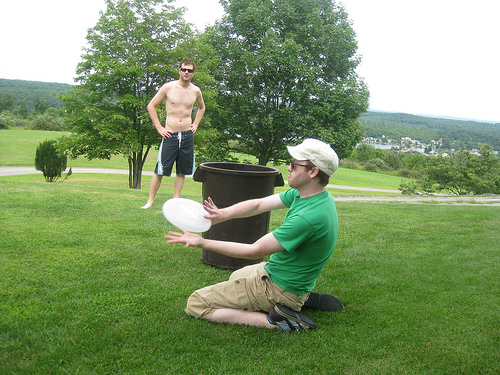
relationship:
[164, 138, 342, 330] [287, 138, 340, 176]
man wearing hat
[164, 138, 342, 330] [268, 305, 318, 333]
man wearing shoe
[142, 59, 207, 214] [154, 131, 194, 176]
man wearing shorts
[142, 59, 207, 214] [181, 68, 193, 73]
man wearing sunglasses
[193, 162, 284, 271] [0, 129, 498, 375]
garbage can sitting on grass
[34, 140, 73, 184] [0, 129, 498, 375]
bush growing in grass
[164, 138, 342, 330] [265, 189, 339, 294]
man wearing shirt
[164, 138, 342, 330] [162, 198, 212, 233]
man tossing frisbee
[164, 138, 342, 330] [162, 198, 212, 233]
man catches frisbee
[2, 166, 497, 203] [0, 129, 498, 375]
sidewalk cutting through grass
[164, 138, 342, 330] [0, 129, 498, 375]
man on grass